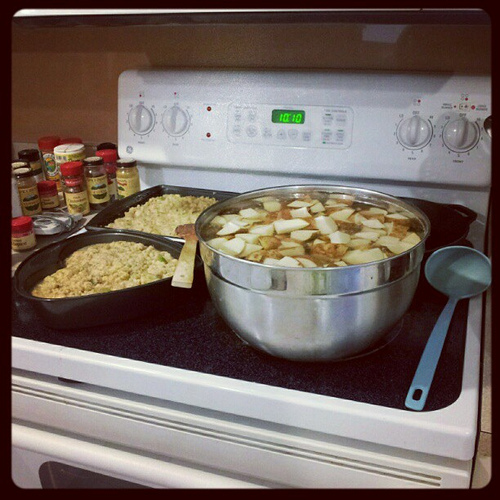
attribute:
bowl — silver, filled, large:
[194, 184, 423, 363]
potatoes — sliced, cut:
[211, 192, 419, 273]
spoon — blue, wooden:
[406, 245, 491, 409]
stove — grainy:
[7, 187, 481, 416]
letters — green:
[275, 111, 300, 125]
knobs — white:
[123, 103, 190, 137]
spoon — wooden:
[172, 225, 198, 287]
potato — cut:
[275, 217, 305, 236]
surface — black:
[109, 282, 462, 411]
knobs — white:
[394, 111, 481, 151]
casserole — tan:
[37, 236, 173, 301]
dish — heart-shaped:
[10, 231, 201, 332]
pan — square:
[90, 183, 237, 248]